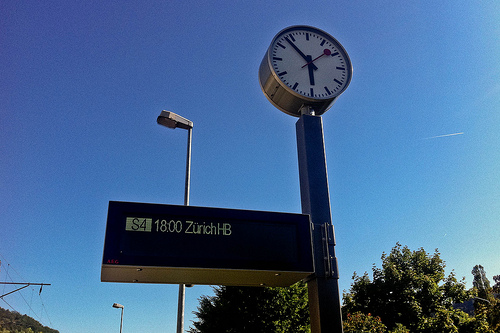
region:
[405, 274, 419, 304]
the tree is tall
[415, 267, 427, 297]
the tree is tall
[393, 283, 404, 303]
the tree is tall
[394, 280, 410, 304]
the tree is tall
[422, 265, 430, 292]
the tree is tall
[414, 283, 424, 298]
the tree is tall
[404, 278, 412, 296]
the tree is tall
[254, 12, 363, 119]
Silver, black and white clock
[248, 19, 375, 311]
The clock is on top of a pole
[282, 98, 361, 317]
The pole is silver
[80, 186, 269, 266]
The sign says S4 18:00 Zurich HB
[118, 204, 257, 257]
The letters are yellow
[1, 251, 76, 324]
Black wires are connected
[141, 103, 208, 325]
Tall black street light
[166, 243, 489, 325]
Trees behind the clock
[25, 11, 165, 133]
Bright blue sky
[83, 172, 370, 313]
Sign is attached to the silver pole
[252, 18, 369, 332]
a clock on a stick, potentially in zurich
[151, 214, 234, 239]
'18:00 zurich hb' in white on black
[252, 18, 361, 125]
clock is typical swiss railway clock, designed by hans hilfiker, made by mobatime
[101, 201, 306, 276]
's4' in black on white on black; all of these non-print colours are rectangular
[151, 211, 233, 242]
zurich hb, btw, is the central station of the largest railway in switzerland. i think the 18:00 would indicate time a train is arriving or departing. from or to zurich hb? who can tell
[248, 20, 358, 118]
it's seven minutes of six, according to our round clock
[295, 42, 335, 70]
second hand on clock is nicely red, w/ a big circle at the end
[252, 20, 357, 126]
the other hands are just plain black rectangles, as are the numbers on the clock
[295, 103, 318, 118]
a little silvertone neck attaches the clock to its long pole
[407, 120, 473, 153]
a tiny line of skywriting in the sky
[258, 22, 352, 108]
the round clock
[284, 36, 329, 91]
the black hands on the clock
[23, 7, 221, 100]
the clear blue sky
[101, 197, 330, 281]
the sign attached to the pole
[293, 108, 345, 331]
the pole holding up the clock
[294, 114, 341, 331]
the pole that is holding up the sign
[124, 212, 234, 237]
the letter and numbers on the sign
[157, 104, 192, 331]
the street light closest to the clock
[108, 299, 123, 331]
the street light furthest from the clock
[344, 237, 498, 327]
the tall green trees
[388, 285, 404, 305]
the tress are tall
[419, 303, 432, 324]
the tress are tall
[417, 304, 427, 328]
the tress are tall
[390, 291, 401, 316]
the tress are tall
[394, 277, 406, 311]
the tress are tall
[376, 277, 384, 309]
the tress are tall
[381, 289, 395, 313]
the tress are tall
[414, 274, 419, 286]
the tress are tall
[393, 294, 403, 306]
the tress are tall